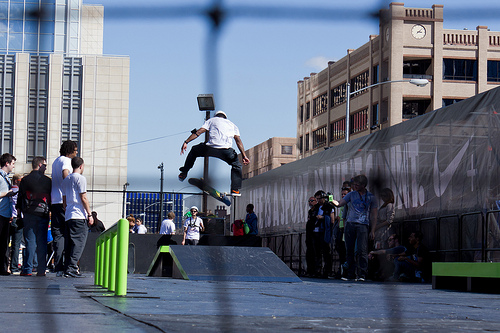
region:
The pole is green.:
[73, 221, 161, 301]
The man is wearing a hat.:
[175, 107, 275, 206]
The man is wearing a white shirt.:
[152, 98, 269, 232]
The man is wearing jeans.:
[157, 121, 275, 216]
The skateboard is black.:
[167, 160, 262, 219]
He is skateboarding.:
[149, 100, 281, 217]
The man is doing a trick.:
[145, 101, 281, 222]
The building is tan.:
[71, 58, 144, 204]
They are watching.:
[0, 176, 97, 293]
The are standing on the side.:
[286, 168, 423, 280]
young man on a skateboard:
[177, 103, 246, 206]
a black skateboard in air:
[184, 172, 234, 205]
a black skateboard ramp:
[141, 237, 296, 284]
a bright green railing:
[90, 216, 130, 294]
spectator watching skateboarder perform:
[64, 154, 92, 278]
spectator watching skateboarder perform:
[48, 135, 77, 260]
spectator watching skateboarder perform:
[18, 154, 52, 278]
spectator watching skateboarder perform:
[0, 148, 24, 275]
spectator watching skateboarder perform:
[182, 205, 202, 241]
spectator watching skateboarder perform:
[156, 211, 176, 232]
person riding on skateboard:
[157, 83, 257, 230]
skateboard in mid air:
[183, 173, 233, 217]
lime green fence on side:
[75, 225, 134, 297]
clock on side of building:
[408, 25, 429, 40]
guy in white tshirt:
[60, 158, 88, 278]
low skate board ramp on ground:
[144, 238, 307, 288]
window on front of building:
[21, 33, 42, 51]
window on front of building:
[8, 35, 22, 50]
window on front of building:
[41, 36, 55, 50]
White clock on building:
[410, 24, 425, 38]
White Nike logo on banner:
[432, 127, 477, 199]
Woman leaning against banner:
[374, 184, 396, 245]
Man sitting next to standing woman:
[366, 231, 405, 279]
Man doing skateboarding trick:
[173, 110, 249, 200]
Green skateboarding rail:
[95, 213, 137, 298]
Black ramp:
[160, 243, 306, 283]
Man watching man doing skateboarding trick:
[58, 150, 95, 277]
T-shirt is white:
[60, 169, 92, 219]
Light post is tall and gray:
[342, 75, 432, 143]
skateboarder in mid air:
[178, 110, 248, 209]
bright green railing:
[92, 218, 130, 292]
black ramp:
[146, 243, 300, 283]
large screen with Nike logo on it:
[241, 85, 498, 265]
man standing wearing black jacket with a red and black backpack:
[15, 155, 53, 276]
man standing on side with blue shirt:
[317, 173, 376, 281]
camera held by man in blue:
[317, 189, 332, 201]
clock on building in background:
[409, 24, 426, 38]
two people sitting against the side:
[365, 232, 427, 282]